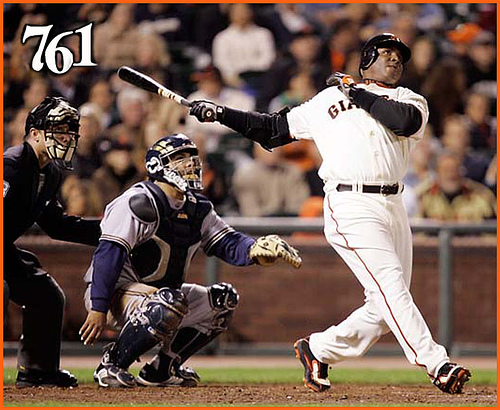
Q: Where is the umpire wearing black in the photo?
A: Behind catcher.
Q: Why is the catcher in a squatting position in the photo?
A: Waiting to catch the baseball.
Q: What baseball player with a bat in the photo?
A: Batter in orange, black and white shoes.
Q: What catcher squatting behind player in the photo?
A: Catcher in need guards.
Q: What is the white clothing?
A: Uniform.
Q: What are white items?
A: Pants.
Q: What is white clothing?
A: Shirt.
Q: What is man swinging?
A: Bat.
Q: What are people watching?
A: Baseball.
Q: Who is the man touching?
A: Catcher.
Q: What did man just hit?
A: Baseball.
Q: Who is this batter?
A: Barry Bonds.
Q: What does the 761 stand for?
A: Homerun count.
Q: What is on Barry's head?
A: Helmet.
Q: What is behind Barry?
A: Catcher.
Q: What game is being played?
A: Baseball.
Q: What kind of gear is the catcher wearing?
A: Protective gear.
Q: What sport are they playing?
A: Baseball.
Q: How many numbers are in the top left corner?
A: Three.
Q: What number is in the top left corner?
A: 761.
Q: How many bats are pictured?
A: One.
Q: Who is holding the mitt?
A: The catcher.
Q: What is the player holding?
A: Baseball bat.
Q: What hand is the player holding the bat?
A: Right hand.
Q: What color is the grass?
A: Green.